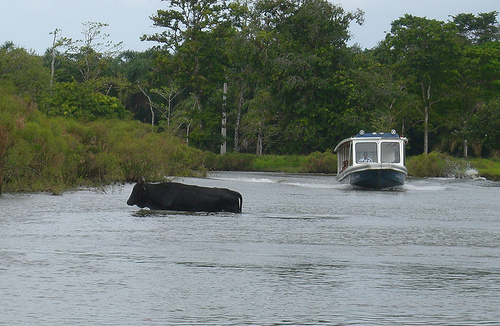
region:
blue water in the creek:
[65, 221, 340, 311]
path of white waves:
[238, 169, 326, 198]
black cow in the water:
[118, 178, 270, 223]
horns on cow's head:
[131, 172, 149, 186]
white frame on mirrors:
[346, 134, 416, 169]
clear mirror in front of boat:
[363, 146, 398, 160]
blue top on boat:
[344, 117, 407, 139]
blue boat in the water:
[333, 120, 421, 200]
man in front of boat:
[351, 145, 376, 165]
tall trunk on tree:
[211, 63, 235, 157]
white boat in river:
[333, 127, 424, 191]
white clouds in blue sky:
[19, 10, 41, 36]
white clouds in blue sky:
[59, 1, 124, 41]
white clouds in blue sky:
[113, 4, 163, 44]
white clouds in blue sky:
[355, 3, 381, 30]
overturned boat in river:
[126, 166, 242, 221]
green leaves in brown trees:
[41, 103, 76, 128]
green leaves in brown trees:
[141, 110, 173, 138]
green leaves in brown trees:
[230, 55, 267, 77]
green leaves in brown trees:
[271, 34, 316, 87]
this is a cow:
[98, 138, 250, 263]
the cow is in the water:
[105, 151, 295, 282]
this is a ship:
[280, 113, 425, 213]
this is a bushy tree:
[82, 108, 204, 190]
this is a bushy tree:
[8, 95, 76, 205]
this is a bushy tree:
[61, 29, 128, 130]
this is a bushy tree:
[125, 53, 207, 177]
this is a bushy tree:
[141, 0, 233, 98]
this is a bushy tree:
[247, 23, 359, 171]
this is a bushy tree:
[387, 21, 461, 162]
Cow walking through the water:
[122, 173, 252, 229]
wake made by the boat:
[228, 169, 463, 200]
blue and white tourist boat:
[331, 123, 411, 195]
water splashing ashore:
[437, 156, 484, 186]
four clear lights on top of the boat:
[355, 125, 402, 139]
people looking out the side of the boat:
[333, 154, 358, 172]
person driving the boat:
[357, 147, 378, 169]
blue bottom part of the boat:
[329, 164, 429, 194]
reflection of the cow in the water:
[125, 207, 242, 228]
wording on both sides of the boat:
[347, 171, 409, 185]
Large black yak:
[125, 174, 244, 216]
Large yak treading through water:
[124, 176, 244, 214]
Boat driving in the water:
[334, 127, 410, 189]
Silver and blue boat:
[333, 128, 410, 191]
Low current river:
[0, 168, 497, 323]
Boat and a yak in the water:
[122, 128, 411, 219]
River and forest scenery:
[0, 1, 497, 323]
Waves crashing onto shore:
[438, 155, 481, 184]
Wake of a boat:
[215, 171, 457, 193]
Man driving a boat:
[356, 149, 373, 164]